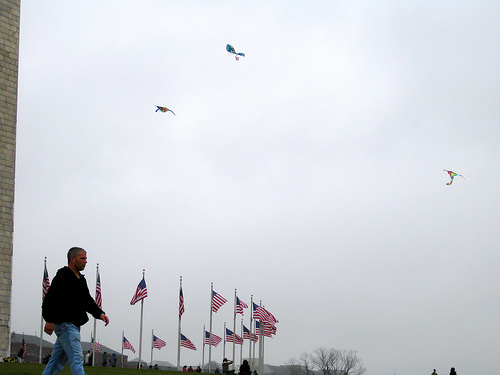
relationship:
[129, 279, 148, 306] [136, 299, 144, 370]
american flag on pole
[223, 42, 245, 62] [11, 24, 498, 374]
kite in sky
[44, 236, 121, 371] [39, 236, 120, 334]
jacket on man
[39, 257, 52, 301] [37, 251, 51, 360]
flag on a pole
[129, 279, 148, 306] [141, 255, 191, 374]
american flag on a pole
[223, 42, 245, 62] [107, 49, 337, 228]
kite in air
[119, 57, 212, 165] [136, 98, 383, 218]
kite in air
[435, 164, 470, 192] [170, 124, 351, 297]
kite in air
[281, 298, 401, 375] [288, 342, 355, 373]
top of a leafless tree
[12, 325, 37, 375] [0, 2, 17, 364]
edge of a building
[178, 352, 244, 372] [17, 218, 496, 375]
people are standing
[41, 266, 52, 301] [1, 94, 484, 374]
flag around washington monument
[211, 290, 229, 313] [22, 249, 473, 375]
american flag around washington monument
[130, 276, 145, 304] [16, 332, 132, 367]
american flag around washington monument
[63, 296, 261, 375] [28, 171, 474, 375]
flag around washington monument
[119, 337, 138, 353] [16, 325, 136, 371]
american flag around washington monument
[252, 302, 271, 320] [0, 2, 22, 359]
american flag around washington monument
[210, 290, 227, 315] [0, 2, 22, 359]
american flag around washington monument